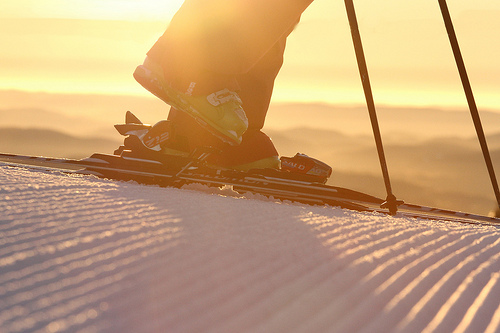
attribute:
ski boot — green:
[139, 44, 254, 148]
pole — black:
[340, 0, 404, 213]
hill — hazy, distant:
[1, 85, 498, 132]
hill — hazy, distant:
[2, 105, 497, 200]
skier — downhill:
[100, 2, 330, 209]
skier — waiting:
[136, 0, 316, 181]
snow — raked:
[2, 147, 498, 329]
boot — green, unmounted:
[136, 51, 250, 143]